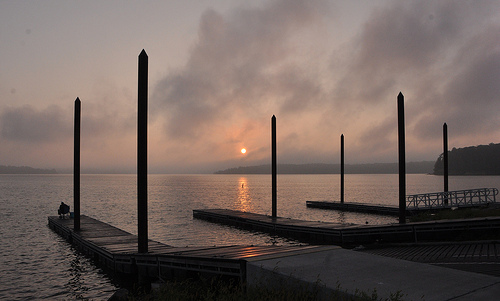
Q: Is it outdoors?
A: Yes, it is outdoors.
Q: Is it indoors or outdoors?
A: It is outdoors.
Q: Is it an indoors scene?
A: No, it is outdoors.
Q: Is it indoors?
A: No, it is outdoors.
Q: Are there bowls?
A: No, there are no bowls.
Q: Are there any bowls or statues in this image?
A: No, there are no bowls or statues.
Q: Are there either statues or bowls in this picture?
A: No, there are no bowls or statues.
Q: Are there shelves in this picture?
A: No, there are no shelves.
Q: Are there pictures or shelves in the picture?
A: No, there are no shelves or pictures.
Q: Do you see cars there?
A: No, there are no cars.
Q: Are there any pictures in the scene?
A: No, there are no pictures.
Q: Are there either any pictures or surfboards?
A: No, there are no pictures or surfboards.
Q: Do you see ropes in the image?
A: No, there are no ropes.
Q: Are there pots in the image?
A: No, there are no pots.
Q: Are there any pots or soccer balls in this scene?
A: No, there are no pots or soccer balls.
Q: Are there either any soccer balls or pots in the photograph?
A: No, there are no pots or soccer balls.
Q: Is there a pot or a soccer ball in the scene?
A: No, there are no pots or soccer balls.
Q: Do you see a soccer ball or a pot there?
A: No, there are no pots or soccer balls.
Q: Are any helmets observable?
A: No, there are no helmets.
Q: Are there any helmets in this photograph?
A: No, there are no helmets.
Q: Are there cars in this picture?
A: No, there are no cars.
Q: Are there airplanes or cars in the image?
A: No, there are no cars or airplanes.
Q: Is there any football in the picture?
A: No, there are no footballs.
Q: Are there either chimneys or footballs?
A: No, there are no footballs or chimneys.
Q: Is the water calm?
A: Yes, the water is calm.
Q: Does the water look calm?
A: Yes, the water is calm.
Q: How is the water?
A: The water is calm.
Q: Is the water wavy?
A: No, the water is calm.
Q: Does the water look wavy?
A: No, the water is calm.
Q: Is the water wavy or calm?
A: The water is calm.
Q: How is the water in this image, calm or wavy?
A: The water is calm.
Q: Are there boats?
A: Yes, there is a boat.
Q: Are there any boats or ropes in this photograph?
A: Yes, there is a boat.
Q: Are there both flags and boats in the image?
A: No, there is a boat but no flags.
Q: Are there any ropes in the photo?
A: No, there are no ropes.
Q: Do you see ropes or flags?
A: No, there are no ropes or flags.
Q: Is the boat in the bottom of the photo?
A: Yes, the boat is in the bottom of the image.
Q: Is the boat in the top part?
A: No, the boat is in the bottom of the image.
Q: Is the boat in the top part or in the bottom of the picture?
A: The boat is in the bottom of the image.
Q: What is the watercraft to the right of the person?
A: The watercraft is a boat.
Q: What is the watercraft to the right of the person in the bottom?
A: The watercraft is a boat.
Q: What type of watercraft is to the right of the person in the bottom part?
A: The watercraft is a boat.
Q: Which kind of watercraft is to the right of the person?
A: The watercraft is a boat.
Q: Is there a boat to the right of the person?
A: Yes, there is a boat to the right of the person.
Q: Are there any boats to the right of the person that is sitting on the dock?
A: Yes, there is a boat to the right of the person.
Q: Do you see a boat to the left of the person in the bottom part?
A: No, the boat is to the right of the person.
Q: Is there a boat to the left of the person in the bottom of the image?
A: No, the boat is to the right of the person.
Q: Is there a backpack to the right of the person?
A: No, there is a boat to the right of the person.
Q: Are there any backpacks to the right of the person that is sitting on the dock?
A: No, there is a boat to the right of the person.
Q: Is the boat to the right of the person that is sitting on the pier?
A: Yes, the boat is to the right of the person.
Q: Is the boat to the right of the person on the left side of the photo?
A: Yes, the boat is to the right of the person.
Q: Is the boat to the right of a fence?
A: No, the boat is to the right of the person.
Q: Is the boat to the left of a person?
A: No, the boat is to the right of a person.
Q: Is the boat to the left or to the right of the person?
A: The boat is to the right of the person.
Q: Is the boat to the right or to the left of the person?
A: The boat is to the right of the person.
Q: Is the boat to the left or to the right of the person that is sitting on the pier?
A: The boat is to the right of the person.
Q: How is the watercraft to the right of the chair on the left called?
A: The watercraft is a boat.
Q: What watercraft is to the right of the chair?
A: The watercraft is a boat.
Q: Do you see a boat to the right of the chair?
A: Yes, there is a boat to the right of the chair.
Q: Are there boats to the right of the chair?
A: Yes, there is a boat to the right of the chair.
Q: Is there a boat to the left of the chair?
A: No, the boat is to the right of the chair.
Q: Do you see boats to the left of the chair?
A: No, the boat is to the right of the chair.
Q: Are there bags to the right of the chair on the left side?
A: No, there is a boat to the right of the chair.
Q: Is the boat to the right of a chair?
A: Yes, the boat is to the right of a chair.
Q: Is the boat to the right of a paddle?
A: No, the boat is to the right of a chair.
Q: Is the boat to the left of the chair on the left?
A: No, the boat is to the right of the chair.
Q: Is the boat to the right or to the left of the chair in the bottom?
A: The boat is to the right of the chair.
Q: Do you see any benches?
A: No, there are no benches.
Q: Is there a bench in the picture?
A: No, there are no benches.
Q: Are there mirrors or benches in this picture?
A: No, there are no benches or mirrors.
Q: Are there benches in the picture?
A: No, there are no benches.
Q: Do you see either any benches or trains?
A: No, there are no benches or trains.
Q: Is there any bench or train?
A: No, there are no benches or trains.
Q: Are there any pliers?
A: No, there are no pliers.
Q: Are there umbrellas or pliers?
A: No, there are no pliers or umbrellas.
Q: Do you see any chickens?
A: No, there are no chickens.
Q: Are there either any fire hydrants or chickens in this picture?
A: No, there are no chickens or fire hydrants.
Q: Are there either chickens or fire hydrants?
A: No, there are no chickens or fire hydrants.